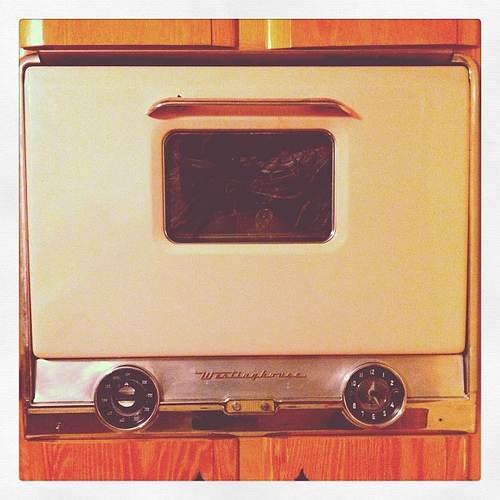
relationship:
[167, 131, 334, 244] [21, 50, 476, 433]
part on stove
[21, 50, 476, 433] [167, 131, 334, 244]
stove has a clear part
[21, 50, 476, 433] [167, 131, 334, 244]
stove has clear part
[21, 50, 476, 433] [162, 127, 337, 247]
stove has a clear part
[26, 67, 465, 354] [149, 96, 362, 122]
door has a handle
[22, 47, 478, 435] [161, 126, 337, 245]
oven has a window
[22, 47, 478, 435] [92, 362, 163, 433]
oven has a dial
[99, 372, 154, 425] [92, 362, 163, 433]
numbers are on dial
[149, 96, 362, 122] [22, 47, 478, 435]
handle on oven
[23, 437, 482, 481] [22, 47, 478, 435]
cabinet underneath oven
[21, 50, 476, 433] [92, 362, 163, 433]
stove has a dial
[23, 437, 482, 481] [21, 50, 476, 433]
cabinet underneath stove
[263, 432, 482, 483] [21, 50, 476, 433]
cabinet underneath stove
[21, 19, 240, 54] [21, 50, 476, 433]
cabinet above stove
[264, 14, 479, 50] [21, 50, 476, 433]
cabinet above stove